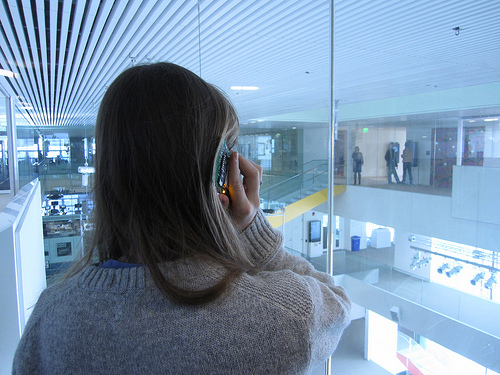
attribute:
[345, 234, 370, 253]
can — blue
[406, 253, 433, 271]
light fixture — white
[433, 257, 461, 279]
light fixture — white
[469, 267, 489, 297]
light fixture — white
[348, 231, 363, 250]
bin — blue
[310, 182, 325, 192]
stair — yellow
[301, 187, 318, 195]
stair — yellow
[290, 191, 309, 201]
stair — yellow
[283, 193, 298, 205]
stair — yellow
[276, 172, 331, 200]
arm rail — silver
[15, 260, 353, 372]
sweater — tan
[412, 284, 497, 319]
carpeting — tan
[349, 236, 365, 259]
trash can — blue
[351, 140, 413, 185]
people — standing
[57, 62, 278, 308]
hair — brown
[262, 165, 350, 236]
stairs — yellow